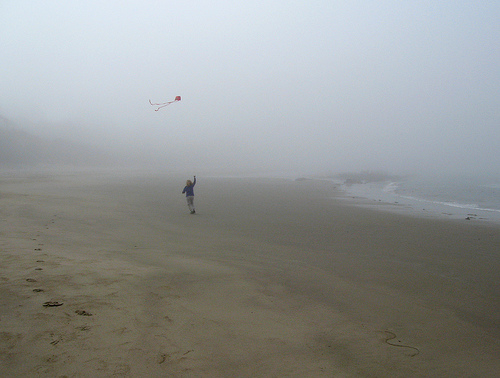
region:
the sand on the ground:
[0, 170, 497, 376]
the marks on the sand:
[1, 189, 418, 374]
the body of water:
[383, 175, 498, 212]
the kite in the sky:
[147, 95, 182, 111]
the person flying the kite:
[182, 173, 195, 214]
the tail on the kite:
[148, 98, 175, 111]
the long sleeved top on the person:
[182, 179, 196, 197]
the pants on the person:
[186, 193, 195, 212]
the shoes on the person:
[190, 208, 195, 213]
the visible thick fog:
[0, 0, 499, 220]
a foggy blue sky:
[386, 55, 443, 111]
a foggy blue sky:
[298, 51, 360, 115]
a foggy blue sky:
[200, 38, 257, 90]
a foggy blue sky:
[79, 62, 113, 105]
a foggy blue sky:
[47, 120, 82, 157]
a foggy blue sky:
[35, 28, 84, 68]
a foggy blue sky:
[369, 118, 456, 186]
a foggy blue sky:
[401, 28, 470, 83]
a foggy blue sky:
[325, 28, 362, 62]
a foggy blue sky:
[64, 37, 111, 86]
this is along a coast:
[30, 19, 467, 363]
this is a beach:
[42, 34, 466, 351]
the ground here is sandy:
[89, 227, 367, 357]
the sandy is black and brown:
[93, 252, 249, 333]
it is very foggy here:
[42, 68, 367, 318]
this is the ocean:
[320, 118, 495, 265]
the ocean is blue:
[361, 124, 489, 245]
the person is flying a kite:
[138, 63, 255, 238]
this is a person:
[147, 169, 264, 265]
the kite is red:
[138, 70, 225, 137]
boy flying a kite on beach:
[140, 95, 206, 218]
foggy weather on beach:
[0, 3, 475, 358]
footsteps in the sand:
[33, 196, 93, 346]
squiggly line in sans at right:
[376, 322, 418, 367]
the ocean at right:
[320, 120, 495, 218]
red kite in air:
[138, 81, 184, 109]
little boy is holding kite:
[176, 173, 206, 211]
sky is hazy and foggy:
[5, 26, 495, 166]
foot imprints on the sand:
[46, 315, 216, 370]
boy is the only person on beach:
[3, 6, 498, 373]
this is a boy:
[178, 172, 205, 207]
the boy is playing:
[176, 169, 205, 210]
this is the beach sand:
[218, 244, 406, 368]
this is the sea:
[395, 168, 452, 199]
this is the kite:
[146, 90, 186, 115]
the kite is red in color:
[148, 92, 181, 111]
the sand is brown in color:
[74, 247, 206, 356]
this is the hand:
[190, 175, 197, 184]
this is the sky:
[256, 5, 401, 106]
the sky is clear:
[277, 11, 382, 111]